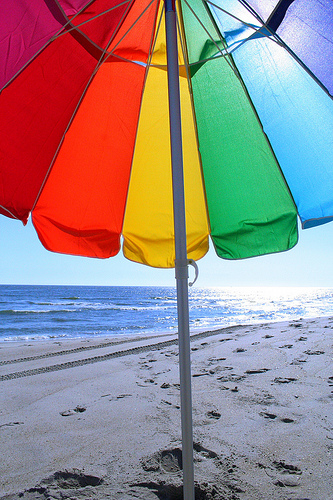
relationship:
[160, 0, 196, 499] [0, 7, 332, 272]
pole for umbrella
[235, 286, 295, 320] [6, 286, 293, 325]
sun reflection reflecting on water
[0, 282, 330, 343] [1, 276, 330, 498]
water at beach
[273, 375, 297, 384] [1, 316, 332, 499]
footprint in sand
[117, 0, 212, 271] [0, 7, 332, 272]
cloth on umbrella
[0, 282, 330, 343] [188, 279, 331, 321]
water reflecting sunlight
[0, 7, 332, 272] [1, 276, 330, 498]
umbrella on beach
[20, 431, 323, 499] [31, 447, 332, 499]
foot prints in sand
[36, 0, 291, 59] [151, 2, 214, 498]
braces connecting pole